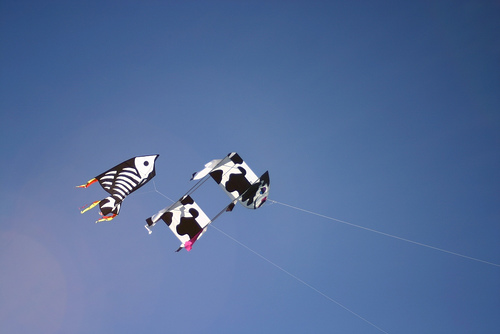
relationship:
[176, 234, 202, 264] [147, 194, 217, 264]
tail on kite